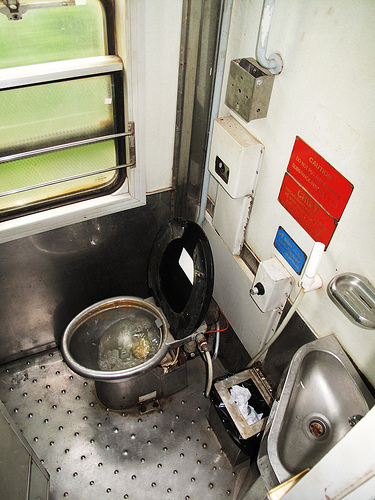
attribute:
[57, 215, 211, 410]
toilet — filthy, small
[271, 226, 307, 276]
sign — blue